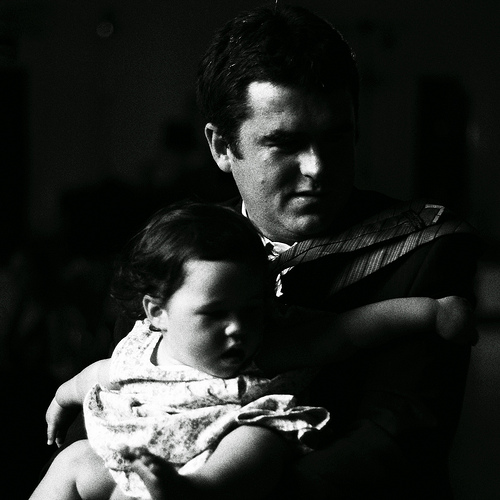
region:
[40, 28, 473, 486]
these are two people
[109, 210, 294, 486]
this is a child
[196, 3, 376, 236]
this is a man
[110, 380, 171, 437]
the cloth is wrinkled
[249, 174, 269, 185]
this is a pimple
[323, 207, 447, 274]
this is a tie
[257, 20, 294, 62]
this is the hair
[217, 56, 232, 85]
the hair is black in color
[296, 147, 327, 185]
this is a nose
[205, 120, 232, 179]
this is an ear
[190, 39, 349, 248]
a man holding a baby.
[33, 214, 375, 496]
a baby being held by a man.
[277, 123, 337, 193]
a nose of a man.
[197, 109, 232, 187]
a man's right ear.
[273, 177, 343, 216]
a man's mouth.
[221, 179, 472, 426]
a jacket on a man.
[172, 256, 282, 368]
a babies face.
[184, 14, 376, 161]
black hair on a man.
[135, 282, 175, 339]
the right ear of a baby.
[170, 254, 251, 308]
the forehead of a baby.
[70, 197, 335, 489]
young child being held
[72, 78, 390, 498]
man holding his young child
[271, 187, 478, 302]
tie blowing in the wind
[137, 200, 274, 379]
infant's face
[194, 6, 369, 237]
face of the father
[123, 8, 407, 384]
father and young girl attention caught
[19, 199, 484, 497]
young child looking at something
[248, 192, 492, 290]
stripped dark tie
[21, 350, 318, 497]
Babies leg and body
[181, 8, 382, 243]
Man looking hard at something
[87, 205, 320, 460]
A baby reaching for something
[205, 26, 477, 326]
A man holding the baby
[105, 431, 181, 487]
The toes of the baby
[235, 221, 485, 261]
The man's neck tie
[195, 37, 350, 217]
The man's face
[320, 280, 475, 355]
Babies hand reaching for soemthing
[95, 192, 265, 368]
The babies head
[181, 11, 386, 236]
the head of a man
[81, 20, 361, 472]
A baby being held by a man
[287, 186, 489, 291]
a mans tie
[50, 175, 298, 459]
a baby in a mans arms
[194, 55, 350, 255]
an adult man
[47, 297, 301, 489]
a dress on a baby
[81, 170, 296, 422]
the head of a baby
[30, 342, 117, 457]
arm and hand of a baby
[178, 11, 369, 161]
a mans hair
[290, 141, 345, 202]
a mans nose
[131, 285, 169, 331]
a baby's ear